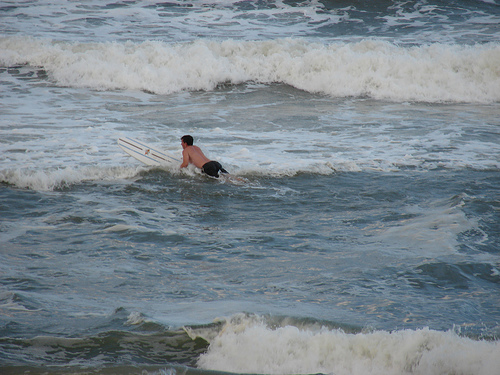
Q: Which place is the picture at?
A: It is at the ocean.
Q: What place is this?
A: It is an ocean.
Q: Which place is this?
A: It is an ocean.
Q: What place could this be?
A: It is an ocean.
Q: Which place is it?
A: It is an ocean.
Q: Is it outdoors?
A: Yes, it is outdoors.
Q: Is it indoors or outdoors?
A: It is outdoors.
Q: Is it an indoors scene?
A: No, it is outdoors.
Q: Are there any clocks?
A: No, there are no clocks.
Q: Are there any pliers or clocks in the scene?
A: No, there are no clocks or pliers.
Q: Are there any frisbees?
A: No, there are no frisbees.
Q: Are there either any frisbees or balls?
A: No, there are no frisbees or balls.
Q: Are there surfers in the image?
A: Yes, there is a surfer.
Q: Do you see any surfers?
A: Yes, there is a surfer.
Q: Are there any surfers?
A: Yes, there is a surfer.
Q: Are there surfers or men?
A: Yes, there is a surfer.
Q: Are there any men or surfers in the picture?
A: Yes, there is a surfer.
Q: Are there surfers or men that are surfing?
A: Yes, the surfer is surfing.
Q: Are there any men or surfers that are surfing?
A: Yes, the surfer is surfing.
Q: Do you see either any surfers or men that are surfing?
A: Yes, the surfer is surfing.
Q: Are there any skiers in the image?
A: No, there are no skiers.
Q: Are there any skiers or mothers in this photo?
A: No, there are no skiers or mothers.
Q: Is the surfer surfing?
A: Yes, the surfer is surfing.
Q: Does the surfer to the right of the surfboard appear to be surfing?
A: Yes, the surfer is surfing.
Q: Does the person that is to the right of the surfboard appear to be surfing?
A: Yes, the surfer is surfing.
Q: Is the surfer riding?
A: No, the surfer is surfing.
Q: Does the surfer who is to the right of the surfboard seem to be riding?
A: No, the surfer is surfing.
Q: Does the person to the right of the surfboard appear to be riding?
A: No, the surfer is surfing.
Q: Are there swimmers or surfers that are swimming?
A: No, there is a surfer but he is surfing.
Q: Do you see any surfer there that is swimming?
A: No, there is a surfer but he is surfing.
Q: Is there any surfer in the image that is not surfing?
A: No, there is a surfer but he is surfing.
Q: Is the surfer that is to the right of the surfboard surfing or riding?
A: The surfer is surfing.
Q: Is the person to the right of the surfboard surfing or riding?
A: The surfer is surfing.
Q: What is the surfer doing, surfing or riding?
A: The surfer is surfing.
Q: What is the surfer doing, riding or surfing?
A: The surfer is surfing.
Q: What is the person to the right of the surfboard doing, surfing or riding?
A: The surfer is surfing.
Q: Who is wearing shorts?
A: The surfer is wearing shorts.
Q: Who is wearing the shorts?
A: The surfer is wearing shorts.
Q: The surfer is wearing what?
A: The surfer is wearing shorts.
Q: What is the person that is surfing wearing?
A: The surfer is wearing shorts.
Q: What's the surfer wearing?
A: The surfer is wearing shorts.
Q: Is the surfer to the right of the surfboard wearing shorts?
A: Yes, the surfer is wearing shorts.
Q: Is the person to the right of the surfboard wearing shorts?
A: Yes, the surfer is wearing shorts.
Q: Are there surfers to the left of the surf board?
A: No, the surfer is to the right of the surf board.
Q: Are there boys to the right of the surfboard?
A: No, there is a surfer to the right of the surfboard.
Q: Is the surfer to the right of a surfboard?
A: Yes, the surfer is to the right of a surfboard.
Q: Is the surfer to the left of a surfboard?
A: No, the surfer is to the right of a surfboard.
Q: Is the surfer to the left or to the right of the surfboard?
A: The surfer is to the right of the surfboard.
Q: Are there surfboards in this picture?
A: Yes, there is a surfboard.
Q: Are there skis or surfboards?
A: Yes, there is a surfboard.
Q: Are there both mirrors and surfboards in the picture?
A: No, there is a surfboard but no mirrors.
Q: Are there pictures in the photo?
A: No, there are no pictures.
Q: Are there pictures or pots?
A: No, there are no pictures or pots.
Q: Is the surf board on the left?
A: Yes, the surf board is on the left of the image.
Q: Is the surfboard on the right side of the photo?
A: No, the surfboard is on the left of the image.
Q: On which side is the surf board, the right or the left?
A: The surf board is on the left of the image.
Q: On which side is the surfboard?
A: The surfboard is on the left of the image.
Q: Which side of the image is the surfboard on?
A: The surfboard is on the left of the image.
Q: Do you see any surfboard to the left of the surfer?
A: Yes, there is a surfboard to the left of the surfer.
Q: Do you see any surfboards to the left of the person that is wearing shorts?
A: Yes, there is a surfboard to the left of the surfer.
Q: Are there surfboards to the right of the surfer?
A: No, the surfboard is to the left of the surfer.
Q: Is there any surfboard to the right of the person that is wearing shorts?
A: No, the surfboard is to the left of the surfer.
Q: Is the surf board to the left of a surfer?
A: Yes, the surf board is to the left of a surfer.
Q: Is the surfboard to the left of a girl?
A: No, the surfboard is to the left of a surfer.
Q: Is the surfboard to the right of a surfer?
A: No, the surfboard is to the left of a surfer.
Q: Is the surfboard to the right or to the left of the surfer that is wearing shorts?
A: The surfboard is to the left of the surfer.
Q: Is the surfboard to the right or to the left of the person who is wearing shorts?
A: The surfboard is to the left of the surfer.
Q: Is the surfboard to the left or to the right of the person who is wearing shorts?
A: The surfboard is to the left of the surfer.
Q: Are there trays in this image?
A: No, there are no trays.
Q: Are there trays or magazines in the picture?
A: No, there are no trays or magazines.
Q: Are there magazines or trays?
A: No, there are no trays or magazines.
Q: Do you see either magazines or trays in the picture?
A: No, there are no trays or magazines.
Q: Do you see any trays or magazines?
A: No, there are no trays or magazines.